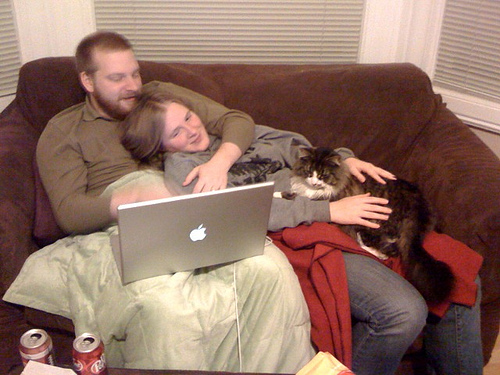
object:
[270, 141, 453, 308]
cat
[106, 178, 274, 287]
laptop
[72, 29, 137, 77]
hair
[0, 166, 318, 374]
blanket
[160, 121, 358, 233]
sweatshirt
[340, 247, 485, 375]
jeans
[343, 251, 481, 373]
jeans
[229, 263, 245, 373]
white cable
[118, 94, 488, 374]
person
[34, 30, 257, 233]
man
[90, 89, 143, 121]
beard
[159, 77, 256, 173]
arm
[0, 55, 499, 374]
couch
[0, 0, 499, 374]
livingroom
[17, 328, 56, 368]
soda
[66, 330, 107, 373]
soda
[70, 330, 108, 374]
can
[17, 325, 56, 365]
can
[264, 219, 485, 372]
blanket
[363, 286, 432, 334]
lap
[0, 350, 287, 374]
table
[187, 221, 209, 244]
logo